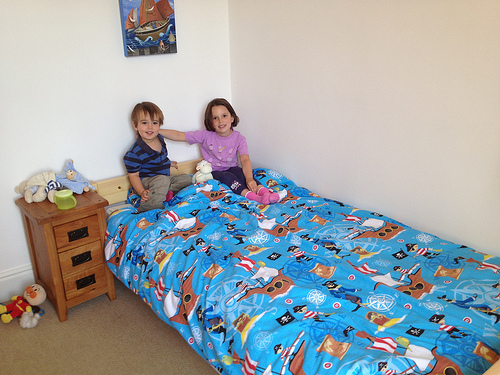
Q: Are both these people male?
A: No, they are both male and female.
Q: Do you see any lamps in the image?
A: No, there are no lamps.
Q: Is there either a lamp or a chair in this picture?
A: No, there are no lamps or chairs.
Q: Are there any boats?
A: Yes, there is a boat.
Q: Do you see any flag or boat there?
A: Yes, there is a boat.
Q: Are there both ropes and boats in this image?
A: No, there is a boat but no ropes.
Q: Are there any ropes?
A: No, there are no ropes.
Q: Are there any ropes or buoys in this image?
A: No, there are no ropes or buoys.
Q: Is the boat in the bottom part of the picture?
A: Yes, the boat is in the bottom of the image.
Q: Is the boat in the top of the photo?
A: No, the boat is in the bottom of the image.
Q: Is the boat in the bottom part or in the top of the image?
A: The boat is in the bottom of the image.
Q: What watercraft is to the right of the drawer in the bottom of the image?
A: The watercraft is a boat.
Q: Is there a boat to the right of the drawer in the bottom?
A: Yes, there is a boat to the right of the drawer.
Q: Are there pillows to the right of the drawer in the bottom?
A: No, there is a boat to the right of the drawer.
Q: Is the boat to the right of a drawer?
A: Yes, the boat is to the right of a drawer.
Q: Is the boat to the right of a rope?
A: No, the boat is to the right of a drawer.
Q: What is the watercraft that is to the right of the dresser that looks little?
A: The watercraft is a boat.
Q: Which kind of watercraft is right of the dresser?
A: The watercraft is a boat.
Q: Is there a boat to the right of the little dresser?
A: Yes, there is a boat to the right of the dresser.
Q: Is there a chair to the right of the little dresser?
A: No, there is a boat to the right of the dresser.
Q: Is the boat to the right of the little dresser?
A: Yes, the boat is to the right of the dresser.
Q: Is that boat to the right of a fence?
A: No, the boat is to the right of the dresser.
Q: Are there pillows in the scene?
A: No, there are no pillows.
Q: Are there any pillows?
A: No, there are no pillows.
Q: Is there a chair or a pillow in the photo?
A: No, there are no pillows or chairs.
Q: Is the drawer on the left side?
A: Yes, the drawer is on the left of the image.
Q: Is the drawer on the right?
A: No, the drawer is on the left of the image.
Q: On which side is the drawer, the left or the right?
A: The drawer is on the left of the image.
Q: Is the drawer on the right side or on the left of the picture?
A: The drawer is on the left of the image.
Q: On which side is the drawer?
A: The drawer is on the left of the image.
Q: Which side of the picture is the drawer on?
A: The drawer is on the left of the image.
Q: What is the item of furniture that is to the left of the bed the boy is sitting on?
A: The piece of furniture is a drawer.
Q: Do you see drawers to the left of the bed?
A: Yes, there is a drawer to the left of the bed.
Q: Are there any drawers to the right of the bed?
A: No, the drawer is to the left of the bed.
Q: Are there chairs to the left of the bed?
A: No, there is a drawer to the left of the bed.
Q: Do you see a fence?
A: No, there are no fences.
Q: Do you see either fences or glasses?
A: No, there are no fences or glasses.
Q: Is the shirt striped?
A: Yes, the shirt is striped.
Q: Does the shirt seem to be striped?
A: Yes, the shirt is striped.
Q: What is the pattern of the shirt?
A: The shirt is striped.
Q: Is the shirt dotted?
A: No, the shirt is striped.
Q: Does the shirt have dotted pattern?
A: No, the shirt is striped.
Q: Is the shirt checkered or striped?
A: The shirt is striped.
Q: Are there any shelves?
A: No, there are no shelves.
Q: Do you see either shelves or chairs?
A: No, there are no shelves or chairs.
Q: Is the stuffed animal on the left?
A: Yes, the stuffed animal is on the left of the image.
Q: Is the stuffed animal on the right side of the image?
A: No, the stuffed animal is on the left of the image.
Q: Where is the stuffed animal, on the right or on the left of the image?
A: The stuffed animal is on the left of the image.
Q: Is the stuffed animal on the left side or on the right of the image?
A: The stuffed animal is on the left of the image.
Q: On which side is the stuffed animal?
A: The stuffed animal is on the left of the image.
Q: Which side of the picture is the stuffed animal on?
A: The stuffed animal is on the left of the image.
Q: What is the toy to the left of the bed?
A: The toy is a stuffed animal.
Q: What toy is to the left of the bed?
A: The toy is a stuffed animal.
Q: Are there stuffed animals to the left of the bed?
A: Yes, there is a stuffed animal to the left of the bed.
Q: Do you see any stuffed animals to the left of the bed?
A: Yes, there is a stuffed animal to the left of the bed.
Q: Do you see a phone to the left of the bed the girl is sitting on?
A: No, there is a stuffed animal to the left of the bed.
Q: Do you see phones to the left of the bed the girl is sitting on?
A: No, there is a stuffed animal to the left of the bed.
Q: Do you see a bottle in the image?
A: No, there are no bottles.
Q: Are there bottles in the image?
A: No, there are no bottles.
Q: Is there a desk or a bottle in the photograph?
A: No, there are no bottles or desks.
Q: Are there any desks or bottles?
A: No, there are no bottles or desks.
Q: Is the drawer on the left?
A: Yes, the drawer is on the left of the image.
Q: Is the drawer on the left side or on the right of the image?
A: The drawer is on the left of the image.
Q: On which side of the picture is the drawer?
A: The drawer is on the left of the image.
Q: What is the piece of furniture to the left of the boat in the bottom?
A: The piece of furniture is a drawer.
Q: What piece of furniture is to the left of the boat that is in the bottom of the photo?
A: The piece of furniture is a drawer.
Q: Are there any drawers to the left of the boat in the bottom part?
A: Yes, there is a drawer to the left of the boat.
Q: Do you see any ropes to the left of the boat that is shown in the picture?
A: No, there is a drawer to the left of the boat.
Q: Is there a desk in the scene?
A: No, there are no desks.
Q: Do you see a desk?
A: No, there are no desks.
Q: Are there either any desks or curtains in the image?
A: No, there are no desks or curtains.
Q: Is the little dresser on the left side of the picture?
A: Yes, the dresser is on the left of the image.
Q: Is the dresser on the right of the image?
A: No, the dresser is on the left of the image.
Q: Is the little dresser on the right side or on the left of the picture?
A: The dresser is on the left of the image.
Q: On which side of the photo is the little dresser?
A: The dresser is on the left of the image.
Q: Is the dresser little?
A: Yes, the dresser is little.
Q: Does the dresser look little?
A: Yes, the dresser is little.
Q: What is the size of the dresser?
A: The dresser is little.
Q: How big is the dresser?
A: The dresser is little.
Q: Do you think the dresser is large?
A: No, the dresser is little.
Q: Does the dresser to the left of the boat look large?
A: No, the dresser is little.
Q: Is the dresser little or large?
A: The dresser is little.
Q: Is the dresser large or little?
A: The dresser is little.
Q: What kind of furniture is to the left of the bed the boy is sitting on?
A: The piece of furniture is a dresser.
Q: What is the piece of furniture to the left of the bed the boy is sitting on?
A: The piece of furniture is a dresser.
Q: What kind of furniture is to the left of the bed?
A: The piece of furniture is a dresser.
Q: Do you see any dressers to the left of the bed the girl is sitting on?
A: Yes, there is a dresser to the left of the bed.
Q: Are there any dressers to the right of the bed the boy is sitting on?
A: No, the dresser is to the left of the bed.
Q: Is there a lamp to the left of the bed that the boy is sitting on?
A: No, there is a dresser to the left of the bed.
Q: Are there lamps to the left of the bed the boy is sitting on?
A: No, there is a dresser to the left of the bed.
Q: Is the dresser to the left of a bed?
A: Yes, the dresser is to the left of a bed.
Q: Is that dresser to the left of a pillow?
A: No, the dresser is to the left of a bed.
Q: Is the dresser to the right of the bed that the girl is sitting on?
A: No, the dresser is to the left of the bed.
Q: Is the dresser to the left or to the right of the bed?
A: The dresser is to the left of the bed.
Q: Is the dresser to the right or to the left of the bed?
A: The dresser is to the left of the bed.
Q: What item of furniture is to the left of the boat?
A: The piece of furniture is a dresser.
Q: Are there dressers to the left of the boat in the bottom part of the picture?
A: Yes, there is a dresser to the left of the boat.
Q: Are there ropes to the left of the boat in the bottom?
A: No, there is a dresser to the left of the boat.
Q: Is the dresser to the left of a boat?
A: Yes, the dresser is to the left of a boat.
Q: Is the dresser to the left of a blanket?
A: No, the dresser is to the left of a boat.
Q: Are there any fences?
A: No, there are no fences.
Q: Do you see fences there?
A: No, there are no fences.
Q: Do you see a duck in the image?
A: Yes, there is a duck.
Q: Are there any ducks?
A: Yes, there is a duck.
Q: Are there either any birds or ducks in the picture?
A: Yes, there is a duck.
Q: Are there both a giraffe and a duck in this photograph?
A: No, there is a duck but no giraffes.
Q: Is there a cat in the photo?
A: No, there are no cats.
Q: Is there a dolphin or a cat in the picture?
A: No, there are no cats or dolphins.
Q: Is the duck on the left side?
A: Yes, the duck is on the left of the image.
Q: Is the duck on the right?
A: No, the duck is on the left of the image.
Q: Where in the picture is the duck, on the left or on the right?
A: The duck is on the left of the image.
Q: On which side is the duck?
A: The duck is on the left of the image.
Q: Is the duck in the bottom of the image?
A: Yes, the duck is in the bottom of the image.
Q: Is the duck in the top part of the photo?
A: No, the duck is in the bottom of the image.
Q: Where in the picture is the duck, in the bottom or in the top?
A: The duck is in the bottom of the image.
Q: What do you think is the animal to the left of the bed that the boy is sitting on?
A: The animal is a duck.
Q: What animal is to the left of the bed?
A: The animal is a duck.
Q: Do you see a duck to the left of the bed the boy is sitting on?
A: Yes, there is a duck to the left of the bed.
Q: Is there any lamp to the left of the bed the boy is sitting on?
A: No, there is a duck to the left of the bed.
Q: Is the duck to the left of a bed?
A: Yes, the duck is to the left of a bed.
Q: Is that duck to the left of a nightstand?
A: No, the duck is to the left of a bed.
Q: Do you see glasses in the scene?
A: No, there are no glasses.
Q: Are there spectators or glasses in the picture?
A: No, there are no glasses or spectators.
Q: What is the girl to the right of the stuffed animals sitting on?
A: The girl is sitting on the bed.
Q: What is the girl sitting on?
A: The girl is sitting on the bed.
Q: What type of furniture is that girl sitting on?
A: The girl is sitting on the bed.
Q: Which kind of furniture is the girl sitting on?
A: The girl is sitting on the bed.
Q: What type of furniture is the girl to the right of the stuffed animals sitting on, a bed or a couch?
A: The girl is sitting on a bed.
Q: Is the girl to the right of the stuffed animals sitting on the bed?
A: Yes, the girl is sitting on the bed.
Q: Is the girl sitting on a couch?
A: No, the girl is sitting on the bed.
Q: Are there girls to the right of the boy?
A: Yes, there is a girl to the right of the boy.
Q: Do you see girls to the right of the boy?
A: Yes, there is a girl to the right of the boy.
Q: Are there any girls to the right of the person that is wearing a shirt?
A: Yes, there is a girl to the right of the boy.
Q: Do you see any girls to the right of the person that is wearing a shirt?
A: Yes, there is a girl to the right of the boy.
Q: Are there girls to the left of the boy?
A: No, the girl is to the right of the boy.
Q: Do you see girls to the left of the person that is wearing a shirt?
A: No, the girl is to the right of the boy.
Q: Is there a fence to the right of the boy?
A: No, there is a girl to the right of the boy.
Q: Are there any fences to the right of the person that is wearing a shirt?
A: No, there is a girl to the right of the boy.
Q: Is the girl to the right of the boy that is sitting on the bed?
A: Yes, the girl is to the right of the boy.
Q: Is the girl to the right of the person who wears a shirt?
A: Yes, the girl is to the right of the boy.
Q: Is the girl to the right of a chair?
A: No, the girl is to the right of the boy.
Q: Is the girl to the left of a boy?
A: No, the girl is to the right of a boy.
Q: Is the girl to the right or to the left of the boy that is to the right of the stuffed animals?
A: The girl is to the right of the boy.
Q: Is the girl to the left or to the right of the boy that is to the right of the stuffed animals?
A: The girl is to the right of the boy.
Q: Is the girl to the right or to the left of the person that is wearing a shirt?
A: The girl is to the right of the boy.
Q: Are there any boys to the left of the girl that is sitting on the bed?
A: Yes, there is a boy to the left of the girl.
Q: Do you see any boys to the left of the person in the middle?
A: Yes, there is a boy to the left of the girl.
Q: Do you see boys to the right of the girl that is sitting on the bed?
A: No, the boy is to the left of the girl.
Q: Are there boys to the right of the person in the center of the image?
A: No, the boy is to the left of the girl.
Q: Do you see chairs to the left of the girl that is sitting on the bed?
A: No, there is a boy to the left of the girl.